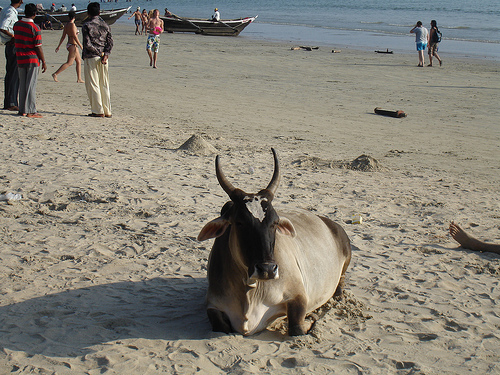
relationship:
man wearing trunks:
[144, 7, 164, 67] [139, 33, 166, 53]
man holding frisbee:
[144, 7, 164, 67] [152, 27, 161, 35]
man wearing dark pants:
[0, 0, 24, 83] [0, 50, 20, 110]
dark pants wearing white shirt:
[0, 50, 20, 110] [0, 7, 20, 38]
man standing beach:
[82, 2, 114, 118] [0, 23, 497, 372]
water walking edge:
[293, 11, 412, 55] [301, 31, 371, 53]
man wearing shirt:
[12, 9, 49, 115] [11, 19, 62, 76]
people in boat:
[8, 8, 169, 120] [157, 5, 265, 33]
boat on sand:
[158, 15, 255, 40] [3, 56, 493, 372]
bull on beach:
[197, 147, 351, 337] [0, 23, 497, 372]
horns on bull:
[214, 147, 284, 197] [193, 147, 352, 339]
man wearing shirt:
[77, 0, 119, 120] [13, 19, 42, 68]